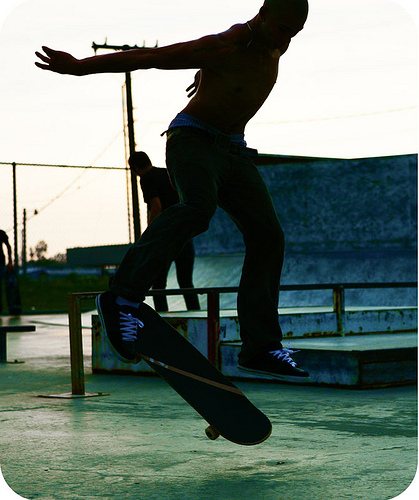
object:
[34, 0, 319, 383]
person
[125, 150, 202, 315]
person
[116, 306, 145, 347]
shoelaces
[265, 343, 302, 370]
shoelaces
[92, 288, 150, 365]
sneaker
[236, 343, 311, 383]
sneaker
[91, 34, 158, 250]
electrical pole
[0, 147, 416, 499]
skateboard park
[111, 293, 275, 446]
skateboard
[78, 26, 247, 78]
arms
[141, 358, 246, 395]
stripe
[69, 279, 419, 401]
railing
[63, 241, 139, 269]
building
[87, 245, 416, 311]
ramp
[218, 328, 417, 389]
steps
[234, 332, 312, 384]
foot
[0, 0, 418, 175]
air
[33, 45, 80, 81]
hands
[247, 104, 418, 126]
powerline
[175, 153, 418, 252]
wall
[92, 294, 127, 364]
soles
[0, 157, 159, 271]
fence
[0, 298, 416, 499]
ground